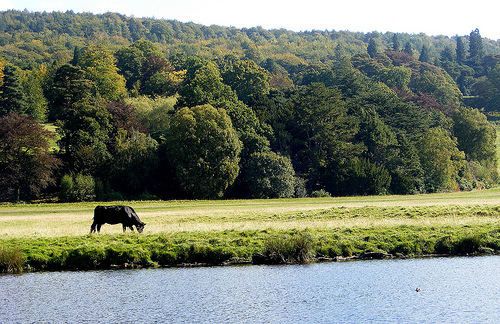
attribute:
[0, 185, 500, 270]
grass — short, bright green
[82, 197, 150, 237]
cow — loose, black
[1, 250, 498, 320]
water — calm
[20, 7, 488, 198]
trees — natural, green, thick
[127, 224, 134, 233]
legs — cow's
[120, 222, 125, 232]
legs — cow's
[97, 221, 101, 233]
legs — cow's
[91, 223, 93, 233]
legs — cow's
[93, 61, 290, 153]
leaves — green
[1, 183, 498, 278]
grass — green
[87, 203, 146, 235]
cow — dark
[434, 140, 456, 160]
leaves — bright-green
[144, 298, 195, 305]
ripples — small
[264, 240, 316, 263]
bush — small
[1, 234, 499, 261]
shore — river's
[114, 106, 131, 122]
leaves — red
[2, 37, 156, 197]
trees — many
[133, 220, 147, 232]
head — cow's